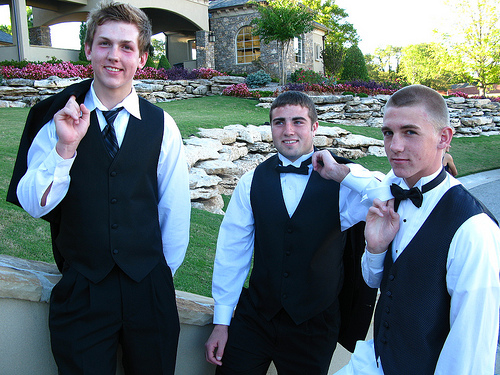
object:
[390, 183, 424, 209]
bow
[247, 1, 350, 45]
flowers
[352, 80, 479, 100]
flowers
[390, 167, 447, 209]
bow tie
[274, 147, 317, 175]
bow tie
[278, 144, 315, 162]
neck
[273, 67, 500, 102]
flowers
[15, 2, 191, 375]
boy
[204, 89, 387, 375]
boy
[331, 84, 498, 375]
boy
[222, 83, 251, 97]
flower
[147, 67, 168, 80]
flower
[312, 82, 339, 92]
flower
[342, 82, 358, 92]
flower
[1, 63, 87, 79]
flower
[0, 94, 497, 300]
grass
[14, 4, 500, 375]
boys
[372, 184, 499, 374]
vest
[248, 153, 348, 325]
vest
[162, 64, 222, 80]
flowers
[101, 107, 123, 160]
tie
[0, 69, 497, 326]
garden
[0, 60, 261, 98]
flowers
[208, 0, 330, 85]
house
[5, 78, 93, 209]
black jacket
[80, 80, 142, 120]
collar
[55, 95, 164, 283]
vest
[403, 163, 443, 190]
neck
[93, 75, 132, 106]
neck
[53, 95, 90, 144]
hand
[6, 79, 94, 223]
jacket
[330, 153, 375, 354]
jacket